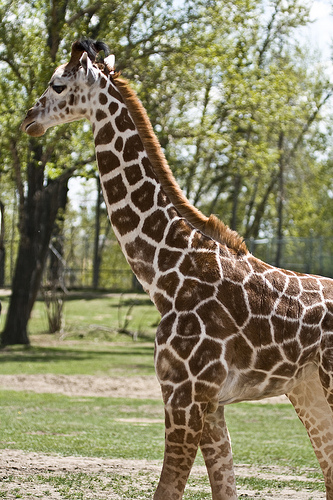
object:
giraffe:
[20, 36, 332, 499]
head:
[20, 36, 121, 139]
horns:
[67, 40, 93, 67]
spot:
[174, 277, 215, 314]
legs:
[152, 403, 202, 499]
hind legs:
[288, 364, 333, 499]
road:
[0, 298, 332, 499]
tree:
[0, 1, 305, 345]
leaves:
[30, 64, 38, 75]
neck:
[86, 110, 204, 305]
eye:
[51, 83, 69, 95]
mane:
[111, 69, 251, 255]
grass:
[0, 295, 331, 499]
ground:
[0, 297, 332, 499]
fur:
[226, 261, 241, 279]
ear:
[79, 50, 91, 75]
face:
[20, 67, 86, 138]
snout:
[24, 106, 36, 119]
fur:
[70, 37, 96, 58]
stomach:
[219, 370, 284, 406]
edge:
[285, 390, 333, 500]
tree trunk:
[0, 188, 57, 341]